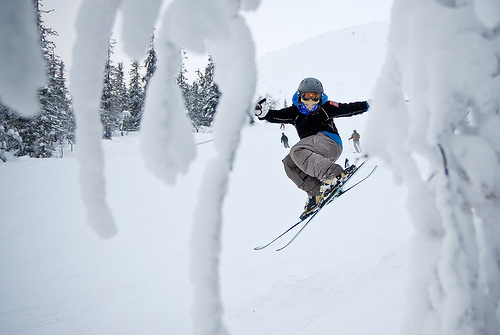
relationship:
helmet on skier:
[294, 75, 324, 103] [254, 74, 373, 215]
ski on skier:
[252, 165, 379, 252] [254, 74, 373, 215]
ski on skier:
[275, 158, 368, 254] [254, 74, 373, 215]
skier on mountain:
[254, 74, 373, 215] [2, 1, 498, 330]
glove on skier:
[253, 95, 272, 120] [254, 74, 373, 215]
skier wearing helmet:
[254, 74, 373, 215] [294, 75, 324, 103]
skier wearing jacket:
[254, 74, 373, 215] [268, 99, 368, 136]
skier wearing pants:
[254, 74, 373, 215] [280, 132, 345, 200]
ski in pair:
[252, 165, 379, 252] [254, 162, 380, 254]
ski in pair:
[275, 158, 368, 254] [254, 162, 380, 254]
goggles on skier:
[302, 92, 321, 102] [254, 74, 373, 215]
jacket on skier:
[268, 99, 368, 136] [254, 74, 373, 215]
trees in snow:
[1, 1, 220, 160] [0, 125, 427, 333]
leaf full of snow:
[364, 4, 497, 329] [363, 3, 453, 223]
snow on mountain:
[256, 19, 414, 111] [12, 18, 485, 320]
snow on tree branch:
[364, 4, 497, 329] [156, 3, 260, 330]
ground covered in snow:
[8, 11, 484, 312] [0, 125, 427, 333]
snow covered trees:
[1, 1, 220, 160] [4, 2, 243, 167]